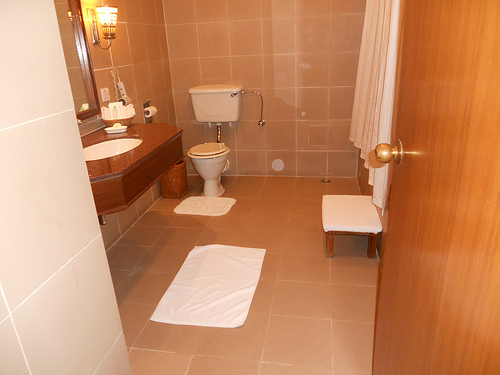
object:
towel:
[148, 243, 266, 329]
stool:
[322, 194, 383, 258]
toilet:
[185, 142, 229, 197]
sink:
[83, 137, 143, 161]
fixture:
[88, 4, 118, 50]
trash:
[160, 159, 190, 199]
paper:
[141, 106, 158, 123]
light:
[94, 7, 118, 37]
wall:
[124, 26, 163, 71]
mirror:
[51, 0, 103, 119]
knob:
[372, 138, 403, 164]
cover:
[321, 193, 382, 233]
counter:
[80, 123, 183, 216]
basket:
[98, 115, 136, 128]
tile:
[262, 179, 308, 210]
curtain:
[348, 0, 400, 213]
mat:
[173, 195, 237, 217]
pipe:
[214, 124, 222, 143]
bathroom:
[55, 0, 500, 374]